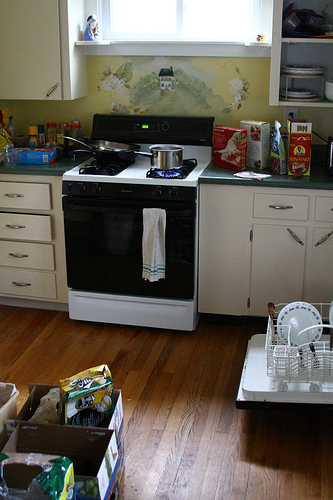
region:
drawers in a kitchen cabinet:
[0, 162, 63, 306]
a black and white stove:
[65, 108, 211, 327]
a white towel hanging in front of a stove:
[140, 204, 169, 283]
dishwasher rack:
[263, 298, 331, 382]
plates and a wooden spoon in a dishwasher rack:
[265, 297, 329, 348]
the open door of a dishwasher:
[236, 322, 330, 410]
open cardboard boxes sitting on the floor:
[5, 366, 126, 496]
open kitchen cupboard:
[271, 1, 330, 106]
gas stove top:
[67, 153, 198, 181]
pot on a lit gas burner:
[133, 142, 189, 180]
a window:
[105, 3, 254, 42]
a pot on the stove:
[61, 129, 140, 158]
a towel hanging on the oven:
[140, 208, 165, 282]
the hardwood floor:
[144, 421, 280, 498]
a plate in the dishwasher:
[278, 305, 320, 347]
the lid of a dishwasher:
[238, 308, 331, 403]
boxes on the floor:
[3, 385, 128, 497]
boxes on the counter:
[211, 117, 310, 169]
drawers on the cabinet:
[3, 183, 60, 296]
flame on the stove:
[157, 167, 178, 176]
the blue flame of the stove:
[152, 166, 184, 180]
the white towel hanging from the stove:
[143, 206, 165, 286]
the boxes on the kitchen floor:
[18, 376, 134, 498]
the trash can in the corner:
[0, 371, 20, 435]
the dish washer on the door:
[262, 298, 332, 387]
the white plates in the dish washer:
[279, 301, 332, 348]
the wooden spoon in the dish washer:
[267, 300, 277, 350]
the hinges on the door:
[243, 227, 256, 310]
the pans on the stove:
[65, 134, 143, 161]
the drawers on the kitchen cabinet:
[0, 177, 58, 299]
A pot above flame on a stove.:
[126, 139, 187, 172]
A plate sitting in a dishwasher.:
[274, 297, 325, 347]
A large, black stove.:
[64, 105, 205, 334]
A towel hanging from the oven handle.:
[138, 202, 166, 287]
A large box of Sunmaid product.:
[283, 117, 313, 177]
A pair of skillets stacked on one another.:
[61, 137, 144, 164]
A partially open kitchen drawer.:
[0, 211, 58, 240]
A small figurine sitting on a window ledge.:
[84, 13, 99, 45]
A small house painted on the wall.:
[156, 63, 176, 95]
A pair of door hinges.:
[245, 228, 253, 310]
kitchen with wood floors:
[1, 3, 330, 496]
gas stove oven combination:
[60, 110, 214, 332]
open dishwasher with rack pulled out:
[237, 291, 328, 419]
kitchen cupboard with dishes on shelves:
[267, 0, 330, 110]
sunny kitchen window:
[97, 1, 271, 46]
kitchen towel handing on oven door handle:
[138, 205, 168, 282]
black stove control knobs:
[65, 182, 181, 200]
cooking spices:
[26, 120, 80, 149]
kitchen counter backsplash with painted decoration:
[0, 54, 298, 138]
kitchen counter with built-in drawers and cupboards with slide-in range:
[0, 111, 332, 333]